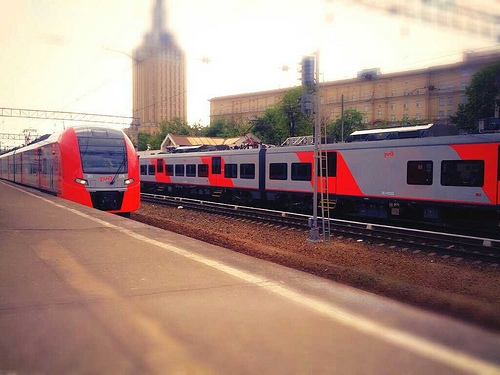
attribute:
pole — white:
[303, 123, 324, 195]